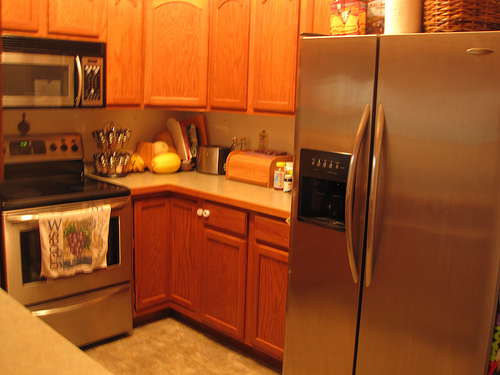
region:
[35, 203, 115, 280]
White towel with image of grapes and words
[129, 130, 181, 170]
Fruit on the counter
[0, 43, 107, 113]
Shiny metal microwave above the stove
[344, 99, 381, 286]
Tall metal handles on the fridge doors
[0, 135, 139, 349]
Silver and black oven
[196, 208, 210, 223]
White circular cupboard handles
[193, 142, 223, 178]
Metallic toaster on the counter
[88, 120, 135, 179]
Rotating spice rack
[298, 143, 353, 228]
Ice and water dispenser on the fridge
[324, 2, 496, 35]
Items on top of the fridge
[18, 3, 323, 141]
kitchen has wooden upper cabinets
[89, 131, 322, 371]
kitchen has wooden lower cabinetsq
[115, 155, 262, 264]
white knobs on draw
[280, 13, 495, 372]
refrigerator is stainless steel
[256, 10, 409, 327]
refrigerator has water despensor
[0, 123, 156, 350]
stove is stainless steel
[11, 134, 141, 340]
stove has towel hanging in front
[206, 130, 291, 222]
bread box is on counter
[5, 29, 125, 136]
microwave is stainless steel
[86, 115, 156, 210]
spice rack is on counter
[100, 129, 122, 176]
salt, and pepper shakers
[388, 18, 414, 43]
Papertowels on top of the fridge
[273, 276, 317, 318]
A stainless steel fridge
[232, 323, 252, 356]
Wood cabinets in the kitchen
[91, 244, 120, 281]
A towel on the stove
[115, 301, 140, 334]
A stainless steel stove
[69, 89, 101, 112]
A stainless steel microwave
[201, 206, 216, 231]
White handle bars to the cabinets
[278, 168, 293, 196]
medicine sitting on the counter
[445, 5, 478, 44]
A basket on top of the fridge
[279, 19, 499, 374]
stainless steel double door in kitchen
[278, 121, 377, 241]
ice maker on fridge door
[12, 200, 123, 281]
kitchen towel hanging over stove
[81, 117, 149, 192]
condiments on rack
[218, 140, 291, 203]
wooden bread bin on counter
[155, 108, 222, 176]
papers on kitchen counter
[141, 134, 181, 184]
squash on counter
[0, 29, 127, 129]
stainless steel and black microwave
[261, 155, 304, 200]
bottles on counter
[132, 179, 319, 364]
wooden cabinet doors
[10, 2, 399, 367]
the cabinets in the kitchen are light wood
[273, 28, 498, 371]
the kitchen has a stainless steel double wide fridge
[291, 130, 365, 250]
water and ice come through the fridge door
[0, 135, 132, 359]
a stainless steel smooth top stove is in the kitchen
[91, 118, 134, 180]
a spice rack is next to the stove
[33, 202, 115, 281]
a kitchen towel is hanging from the oven door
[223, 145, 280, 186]
a wood breadbox is on the counter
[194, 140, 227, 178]
a stainless steel toaster is on the counter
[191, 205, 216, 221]
white knobs are on the cabinets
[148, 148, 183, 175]
a squash is on the counter